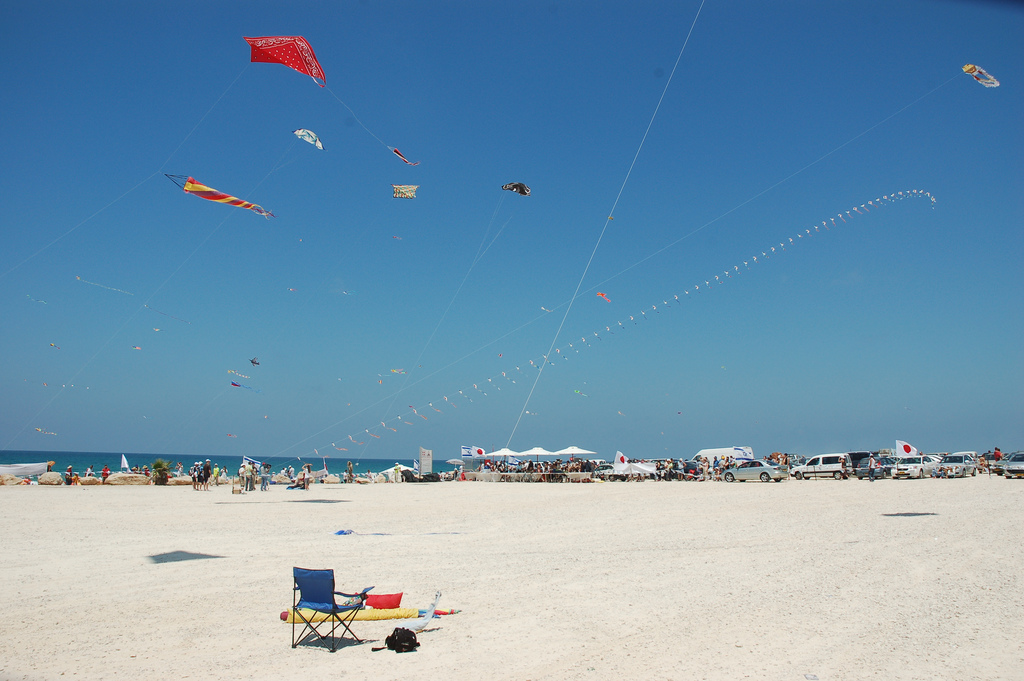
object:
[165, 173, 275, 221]
kite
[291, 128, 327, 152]
kite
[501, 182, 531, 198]
kite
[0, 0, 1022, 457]
air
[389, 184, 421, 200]
kite